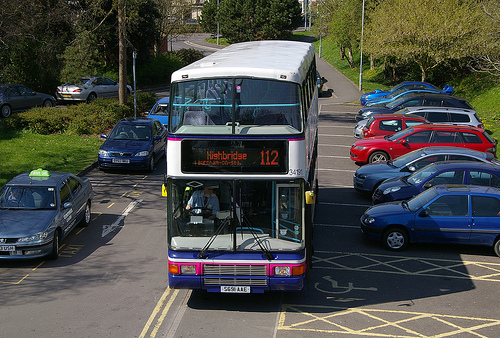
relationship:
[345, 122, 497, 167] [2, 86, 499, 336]
car in parking lot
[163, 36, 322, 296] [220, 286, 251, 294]
bus has license plate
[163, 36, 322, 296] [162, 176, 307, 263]
bus has windshield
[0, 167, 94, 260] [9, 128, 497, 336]
car on road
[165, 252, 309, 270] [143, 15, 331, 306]
white strip front bus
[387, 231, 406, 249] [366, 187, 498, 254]
tire on front of car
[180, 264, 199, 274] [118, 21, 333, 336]
headlight on left side of bus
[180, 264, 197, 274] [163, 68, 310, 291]
headlight on right side of bus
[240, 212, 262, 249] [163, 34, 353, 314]
windshield wiper on front of bus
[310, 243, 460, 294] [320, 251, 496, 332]
shadow on top of ground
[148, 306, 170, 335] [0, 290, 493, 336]
line painted on ground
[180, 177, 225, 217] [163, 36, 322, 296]
driver on bus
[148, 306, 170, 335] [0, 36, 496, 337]
line on ground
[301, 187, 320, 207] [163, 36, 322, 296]
left mirror on bus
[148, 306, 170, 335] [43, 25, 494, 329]
line on road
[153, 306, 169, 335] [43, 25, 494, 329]
line on road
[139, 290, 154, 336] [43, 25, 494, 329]
line on road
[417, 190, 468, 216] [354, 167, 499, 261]
window on side of car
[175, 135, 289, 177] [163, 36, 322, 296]
sign on front of bus